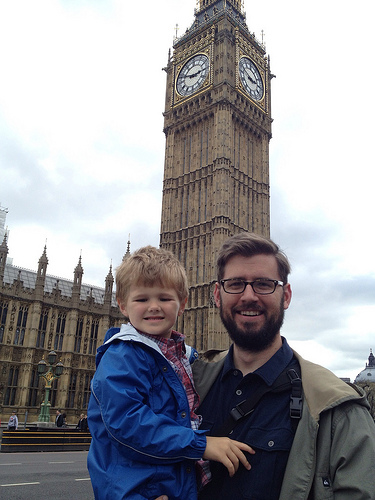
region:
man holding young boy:
[95, 225, 374, 498]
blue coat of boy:
[91, 329, 198, 499]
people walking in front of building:
[6, 407, 89, 431]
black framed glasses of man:
[219, 273, 274, 298]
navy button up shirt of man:
[191, 343, 297, 499]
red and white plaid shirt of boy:
[162, 339, 212, 480]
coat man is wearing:
[200, 343, 371, 498]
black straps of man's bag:
[214, 365, 309, 470]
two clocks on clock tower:
[168, 43, 263, 104]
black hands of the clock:
[173, 47, 267, 105]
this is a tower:
[160, 2, 271, 232]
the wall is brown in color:
[160, 107, 268, 221]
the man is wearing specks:
[219, 274, 280, 293]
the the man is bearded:
[235, 325, 267, 343]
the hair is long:
[227, 230, 263, 251]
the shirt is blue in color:
[257, 404, 285, 464]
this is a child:
[95, 241, 190, 487]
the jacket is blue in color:
[92, 351, 162, 478]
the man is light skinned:
[254, 256, 266, 272]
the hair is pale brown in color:
[135, 251, 164, 284]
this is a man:
[210, 244, 318, 496]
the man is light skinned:
[235, 255, 269, 271]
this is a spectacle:
[212, 275, 282, 294]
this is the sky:
[29, 137, 117, 206]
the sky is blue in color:
[5, 163, 50, 213]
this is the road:
[19, 456, 75, 497]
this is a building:
[171, 46, 259, 223]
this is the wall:
[180, 138, 206, 202]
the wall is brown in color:
[181, 174, 215, 223]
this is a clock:
[181, 60, 202, 84]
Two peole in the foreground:
[77, 222, 373, 498]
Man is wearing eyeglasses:
[206, 231, 296, 346]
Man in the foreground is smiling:
[222, 254, 281, 329]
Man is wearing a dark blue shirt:
[194, 344, 303, 495]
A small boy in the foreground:
[81, 244, 259, 498]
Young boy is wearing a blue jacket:
[75, 317, 212, 493]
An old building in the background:
[1, 204, 273, 430]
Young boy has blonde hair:
[106, 244, 194, 338]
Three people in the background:
[2, 400, 90, 437]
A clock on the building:
[174, 49, 268, 108]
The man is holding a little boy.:
[78, 216, 374, 498]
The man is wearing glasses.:
[195, 211, 326, 386]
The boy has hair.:
[83, 233, 207, 390]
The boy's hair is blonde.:
[82, 232, 197, 388]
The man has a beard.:
[198, 226, 308, 371]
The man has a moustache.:
[200, 226, 303, 366]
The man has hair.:
[199, 223, 305, 366]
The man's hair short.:
[193, 221, 311, 371]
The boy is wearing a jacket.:
[73, 235, 250, 498]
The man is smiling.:
[204, 224, 308, 361]